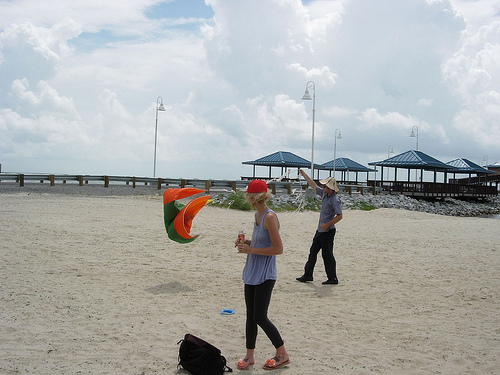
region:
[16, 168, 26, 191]
This is a support pole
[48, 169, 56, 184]
This is a support pole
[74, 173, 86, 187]
This is a support pole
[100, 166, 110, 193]
This is a support pole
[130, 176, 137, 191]
This is a support pole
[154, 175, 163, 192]
This is a support pole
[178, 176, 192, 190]
This is a support pole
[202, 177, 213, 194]
This is a support pole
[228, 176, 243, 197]
This is a support pole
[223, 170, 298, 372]
This is a person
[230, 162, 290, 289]
girl wearing light purple top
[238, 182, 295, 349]
lady wearing black leggings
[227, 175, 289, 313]
lady wearing red cap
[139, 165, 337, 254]
green and orange kite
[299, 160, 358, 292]
guy wearing straw hat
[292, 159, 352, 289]
guy wearing black pants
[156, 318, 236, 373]
black bag on sand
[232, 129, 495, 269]
covered pavilion behind people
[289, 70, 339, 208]
light pole near pavilion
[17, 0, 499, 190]
large white clouds in sky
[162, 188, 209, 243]
orange and green kite floating in mid air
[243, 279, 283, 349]
tight black yoga pants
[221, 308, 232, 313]
blue kite string holder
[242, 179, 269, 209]
red cap on a blonde head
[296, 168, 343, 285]
thin man wearing grey shirt and black pants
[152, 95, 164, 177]
tall grey metal light pole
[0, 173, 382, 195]
long grey metal guard rail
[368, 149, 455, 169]
blue lined pavillion roof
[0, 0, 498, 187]
fluffy white and grey clouds in the blue sky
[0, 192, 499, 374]
sand on the uncrowded beach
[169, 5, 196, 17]
this is the sky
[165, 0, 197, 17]
the sky is blue in color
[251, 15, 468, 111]
the sky has some clouds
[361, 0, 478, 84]
the clouds are white in color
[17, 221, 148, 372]
this is the ground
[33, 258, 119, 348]
the ground is sandy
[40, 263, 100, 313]
the sand is brown in color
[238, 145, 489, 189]
these are some huts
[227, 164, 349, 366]
these are two people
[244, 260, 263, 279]
the vest is grey in color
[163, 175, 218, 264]
the kite is orange and green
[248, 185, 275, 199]
the hat is red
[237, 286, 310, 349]
the apnts are black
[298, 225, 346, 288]
the pants are black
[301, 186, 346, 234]
the top is grey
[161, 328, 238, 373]
the bag is on the floor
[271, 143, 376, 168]
the roof is green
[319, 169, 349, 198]
the hat is white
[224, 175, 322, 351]
she is thin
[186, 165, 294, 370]
she is holding a drink